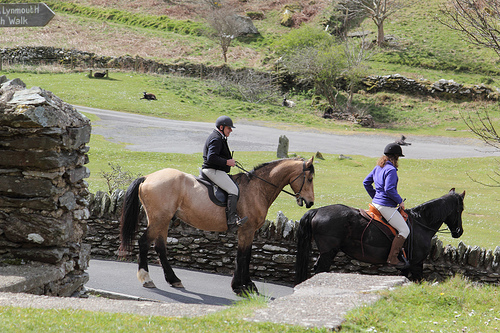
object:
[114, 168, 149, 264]
tail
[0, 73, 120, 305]
stone wall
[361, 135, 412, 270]
person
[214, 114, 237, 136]
helmet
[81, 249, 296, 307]
pavement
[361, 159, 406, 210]
shirt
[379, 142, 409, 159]
hat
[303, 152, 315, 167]
ear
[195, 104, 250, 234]
man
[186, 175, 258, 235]
boots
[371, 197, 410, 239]
pants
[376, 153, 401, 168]
hair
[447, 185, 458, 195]
ear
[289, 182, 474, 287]
horse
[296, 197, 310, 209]
horse's mouth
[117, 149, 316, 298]
horse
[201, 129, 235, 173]
jacket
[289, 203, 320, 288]
tail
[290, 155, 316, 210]
head